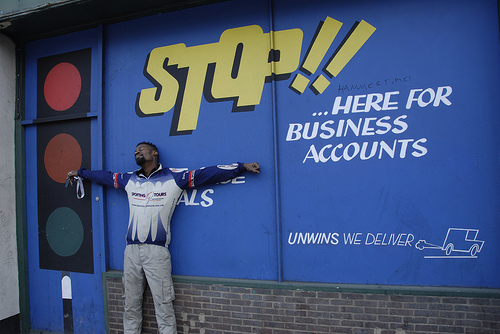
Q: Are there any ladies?
A: No, there are no ladies.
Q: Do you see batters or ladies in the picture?
A: No, there are no ladies or batters.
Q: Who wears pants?
A: The man wears pants.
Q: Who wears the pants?
A: The man wears pants.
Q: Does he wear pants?
A: Yes, the man wears pants.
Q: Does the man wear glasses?
A: No, the man wears pants.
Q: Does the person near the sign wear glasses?
A: No, the man wears pants.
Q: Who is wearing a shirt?
A: The man is wearing a shirt.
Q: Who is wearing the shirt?
A: The man is wearing a shirt.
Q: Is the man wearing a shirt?
A: Yes, the man is wearing a shirt.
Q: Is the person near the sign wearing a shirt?
A: Yes, the man is wearing a shirt.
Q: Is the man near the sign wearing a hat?
A: No, the man is wearing a shirt.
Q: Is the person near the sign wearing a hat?
A: No, the man is wearing a shirt.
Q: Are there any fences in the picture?
A: No, there are no fences.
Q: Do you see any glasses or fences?
A: No, there are no fences or glasses.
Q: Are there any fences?
A: No, there are no fences.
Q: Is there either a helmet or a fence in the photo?
A: No, there are no fences or helmets.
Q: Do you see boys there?
A: No, there are no boys.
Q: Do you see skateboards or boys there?
A: No, there are no boys or skateboards.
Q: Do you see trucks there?
A: Yes, there is a truck.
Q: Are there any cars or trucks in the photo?
A: Yes, there is a truck.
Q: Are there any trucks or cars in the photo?
A: Yes, there is a truck.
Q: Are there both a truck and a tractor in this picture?
A: No, there is a truck but no tractors.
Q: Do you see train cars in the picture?
A: No, there are no train cars.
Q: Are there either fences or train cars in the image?
A: No, there are no train cars or fences.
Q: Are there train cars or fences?
A: No, there are no train cars or fences.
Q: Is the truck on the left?
A: No, the truck is on the right of the image.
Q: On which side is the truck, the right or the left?
A: The truck is on the right of the image.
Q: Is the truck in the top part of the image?
A: No, the truck is in the bottom of the image.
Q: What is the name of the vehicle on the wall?
A: The vehicle is a truck.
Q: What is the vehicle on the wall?
A: The vehicle is a truck.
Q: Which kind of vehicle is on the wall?
A: The vehicle is a truck.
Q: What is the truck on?
A: The truck is on the wall.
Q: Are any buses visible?
A: No, there are no buses.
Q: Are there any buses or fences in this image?
A: No, there are no buses or fences.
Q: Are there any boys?
A: No, there are no boys.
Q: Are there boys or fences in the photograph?
A: No, there are no boys or fences.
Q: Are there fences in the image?
A: No, there are no fences.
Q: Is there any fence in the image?
A: No, there are no fences.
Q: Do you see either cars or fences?
A: No, there are no fences or cars.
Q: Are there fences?
A: No, there are no fences.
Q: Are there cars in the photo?
A: No, there are no cars.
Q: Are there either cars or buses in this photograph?
A: No, there are no cars or buses.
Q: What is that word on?
A: The word is on the wall.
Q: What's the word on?
A: The word is on the wall.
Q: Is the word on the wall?
A: Yes, the word is on the wall.